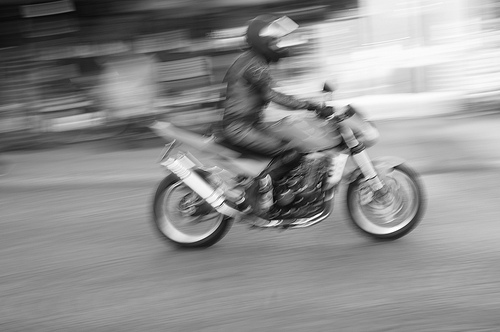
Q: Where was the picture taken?
A: In a city.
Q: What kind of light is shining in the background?
A: Sunlight.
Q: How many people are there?
A: One.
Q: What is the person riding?
A: A motorcycle.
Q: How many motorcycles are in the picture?
A: One.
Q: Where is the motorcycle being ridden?
A: In the street.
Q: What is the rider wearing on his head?
A: A helmet.